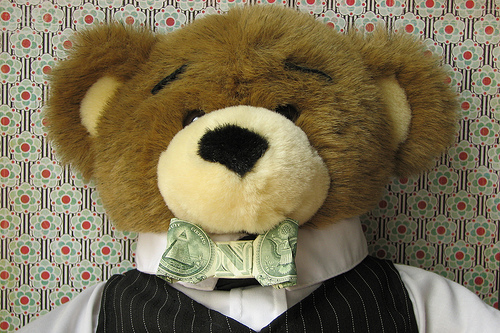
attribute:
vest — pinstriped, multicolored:
[93, 251, 421, 331]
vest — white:
[333, 288, 403, 330]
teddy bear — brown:
[13, 5, 498, 331]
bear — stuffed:
[33, 11, 499, 293]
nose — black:
[191, 117, 276, 184]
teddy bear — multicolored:
[29, 14, 499, 265]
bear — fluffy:
[48, 20, 443, 310]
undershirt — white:
[6, 212, 499, 332]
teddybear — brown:
[7, 212, 499, 332]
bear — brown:
[42, 16, 497, 329]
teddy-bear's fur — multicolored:
[44, 1, 456, 235]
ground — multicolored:
[344, 101, 429, 156]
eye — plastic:
[273, 104, 298, 122]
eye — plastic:
[180, 109, 202, 127]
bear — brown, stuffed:
[6, 8, 498, 330]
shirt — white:
[12, 214, 498, 331]